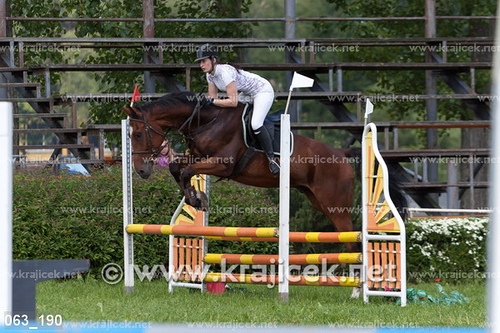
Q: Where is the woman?
A: Riding the horse.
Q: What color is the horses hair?
A: Black.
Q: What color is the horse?
A: Brown.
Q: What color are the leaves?
A: Green.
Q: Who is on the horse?
A: The woman.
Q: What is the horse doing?
A: Leaping over the obstacle.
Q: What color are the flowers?
A: White.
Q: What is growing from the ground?
A: Grass, plants, and flowers.